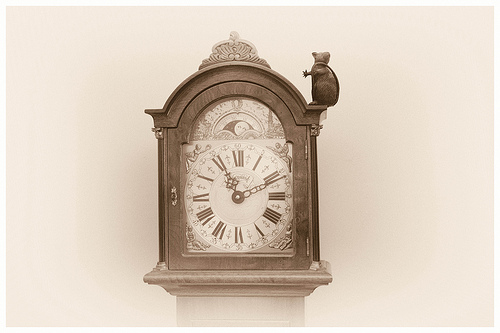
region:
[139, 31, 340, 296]
old fashioned grandfather clock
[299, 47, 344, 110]
wooden clapping rat statue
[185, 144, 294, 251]
analogue clock face with roman numerals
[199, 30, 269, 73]
decorative piece on top of clock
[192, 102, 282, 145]
sleepy moon face art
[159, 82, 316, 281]
glass door over clock face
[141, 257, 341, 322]
pedistol holding the clock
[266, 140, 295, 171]
drawing of people laying on the clock face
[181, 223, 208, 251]
drawing of person under clock face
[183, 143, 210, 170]
drawing of person on top of clock face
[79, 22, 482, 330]
a clock that is inside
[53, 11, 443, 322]
a clock that is old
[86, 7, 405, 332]
a clock on a tower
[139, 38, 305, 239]
an old clock inside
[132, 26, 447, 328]
an old clock on a tower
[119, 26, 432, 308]
a clock with an animal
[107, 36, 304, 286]
an animal on the clock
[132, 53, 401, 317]
a clock with arms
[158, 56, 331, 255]
an old clock with arms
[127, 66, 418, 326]
a clock with numbers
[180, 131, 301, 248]
face of clock has roman numeral numbers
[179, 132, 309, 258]
the time showing is 11:11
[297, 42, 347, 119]
mouse on top of clock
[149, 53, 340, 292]
top of grandfather clock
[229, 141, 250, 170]
roman number for the number twelve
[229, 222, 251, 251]
roman numeral for the number six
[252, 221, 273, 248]
roman numeral for the number five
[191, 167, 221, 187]
roman numeral for the number ten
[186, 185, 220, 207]
roman numeral for the number 9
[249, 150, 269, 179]
roman numeral for the number one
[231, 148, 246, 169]
XII on the clock that marks 12.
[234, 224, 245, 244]
Upside down VI on a clock that marks 6.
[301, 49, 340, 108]
Little mouse on the side of a clock.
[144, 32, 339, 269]
Brown wooden clock with a mouse on the side.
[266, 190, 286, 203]
III on a clock that marks a 3.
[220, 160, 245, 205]
Smaller decorative hand of a clock.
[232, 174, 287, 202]
Longer decorative hand of a clock.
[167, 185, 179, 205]
Little gold knob on the left of a wood clock.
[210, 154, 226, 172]
XI on a clock that marks 11.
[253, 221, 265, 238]
Upside down V on a clock that marks 5.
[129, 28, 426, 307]
an inside clock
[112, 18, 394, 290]
an inside clocl that is old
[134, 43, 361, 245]
an inside clock that is old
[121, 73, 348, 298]
clock with roman numerals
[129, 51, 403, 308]
a clock with roman numerals